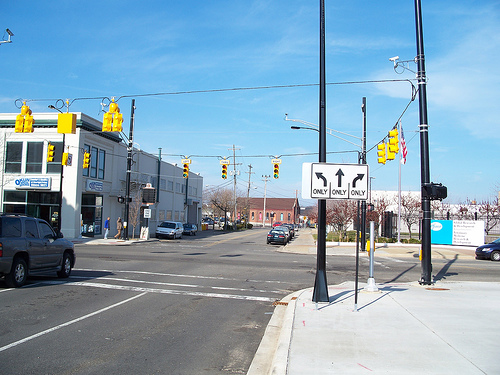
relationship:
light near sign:
[171, 151, 201, 187] [300, 158, 380, 207]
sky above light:
[138, 17, 273, 77] [171, 151, 201, 187]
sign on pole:
[300, 158, 380, 207] [292, 205, 373, 297]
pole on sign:
[292, 205, 373, 297] [300, 158, 380, 207]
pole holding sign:
[292, 205, 373, 297] [300, 158, 380, 207]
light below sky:
[171, 151, 201, 187] [138, 17, 273, 77]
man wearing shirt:
[100, 208, 114, 239] [102, 218, 112, 233]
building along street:
[9, 105, 231, 226] [118, 213, 308, 248]